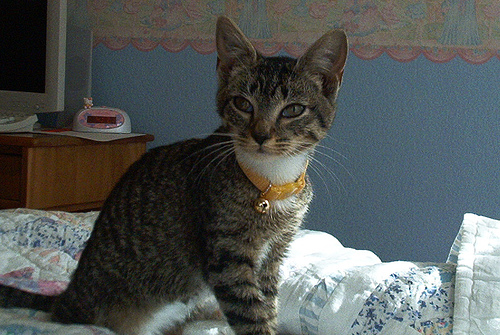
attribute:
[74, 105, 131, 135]
clock — pink, white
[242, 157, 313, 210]
collar — yellow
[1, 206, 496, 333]
comforter — blue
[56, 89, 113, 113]
figure — hello kitty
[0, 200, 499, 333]
blanket — white, blue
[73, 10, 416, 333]
cat — small, tabby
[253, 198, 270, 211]
bell — Gold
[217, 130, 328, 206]
collar — cat's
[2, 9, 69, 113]
frame — white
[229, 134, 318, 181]
neck — white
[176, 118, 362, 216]
whiskers — white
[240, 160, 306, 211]
collar — orange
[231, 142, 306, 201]
collar — yellow, orange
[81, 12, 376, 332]
cat — striped, furry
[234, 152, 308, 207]
collar — cat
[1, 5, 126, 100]
computer — early 2000s, desktop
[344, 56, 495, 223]
wall — pink, blue, white, painted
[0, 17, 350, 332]
cat — striped, grey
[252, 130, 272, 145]
nose — black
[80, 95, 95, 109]
hello kitty — white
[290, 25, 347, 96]
ear — grey, striped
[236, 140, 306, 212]
collar — yellow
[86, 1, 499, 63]
picture — scalloped